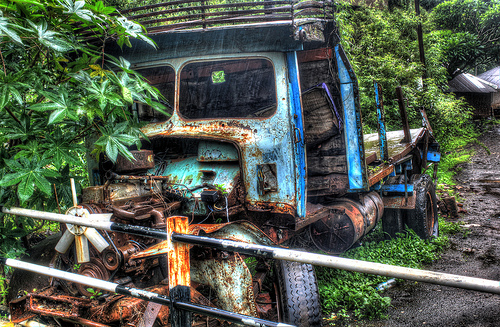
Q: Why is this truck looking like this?
A: Old strap.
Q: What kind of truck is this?
A: A old one.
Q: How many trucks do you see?
A: Only one.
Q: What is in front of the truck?
A: A rail.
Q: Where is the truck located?
A: On side of bushes.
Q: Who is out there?
A: No one.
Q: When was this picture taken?
A: In the daytime.